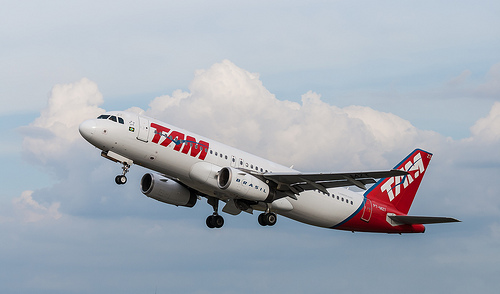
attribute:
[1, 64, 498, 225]
cloud — blue grey, stormy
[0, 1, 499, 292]
sky — shades of blue, light blue, blue, cloudy, day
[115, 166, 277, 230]
landing gear — down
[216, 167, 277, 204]
engine — white, here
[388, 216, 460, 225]
tail wing — stabilizer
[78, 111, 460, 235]
airplane — flying, painted red, whit, here, white, at angle, white bodied, in flight, outdoors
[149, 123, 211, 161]
logo — red, tam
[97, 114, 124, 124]
cockpit window — at front of airplane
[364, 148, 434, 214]
tail — blue bordered, red, white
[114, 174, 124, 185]
wheels — black, down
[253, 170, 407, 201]
wing — white